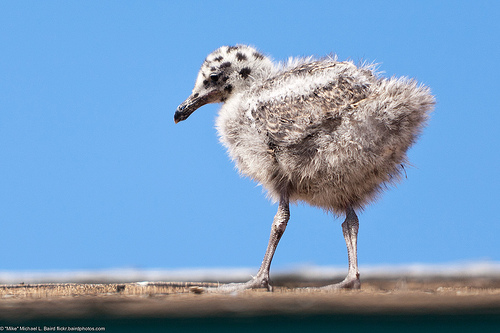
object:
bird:
[173, 43, 438, 292]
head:
[170, 43, 269, 125]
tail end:
[366, 75, 437, 131]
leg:
[218, 193, 291, 292]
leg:
[316, 204, 362, 291]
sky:
[1, 1, 153, 113]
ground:
[0, 265, 500, 333]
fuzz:
[378, 89, 411, 111]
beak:
[173, 87, 219, 123]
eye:
[210, 73, 219, 81]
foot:
[215, 275, 276, 294]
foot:
[319, 273, 361, 291]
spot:
[213, 55, 224, 61]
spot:
[225, 45, 238, 54]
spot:
[220, 61, 232, 69]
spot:
[235, 52, 247, 62]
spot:
[238, 67, 251, 80]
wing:
[248, 62, 367, 147]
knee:
[271, 209, 291, 233]